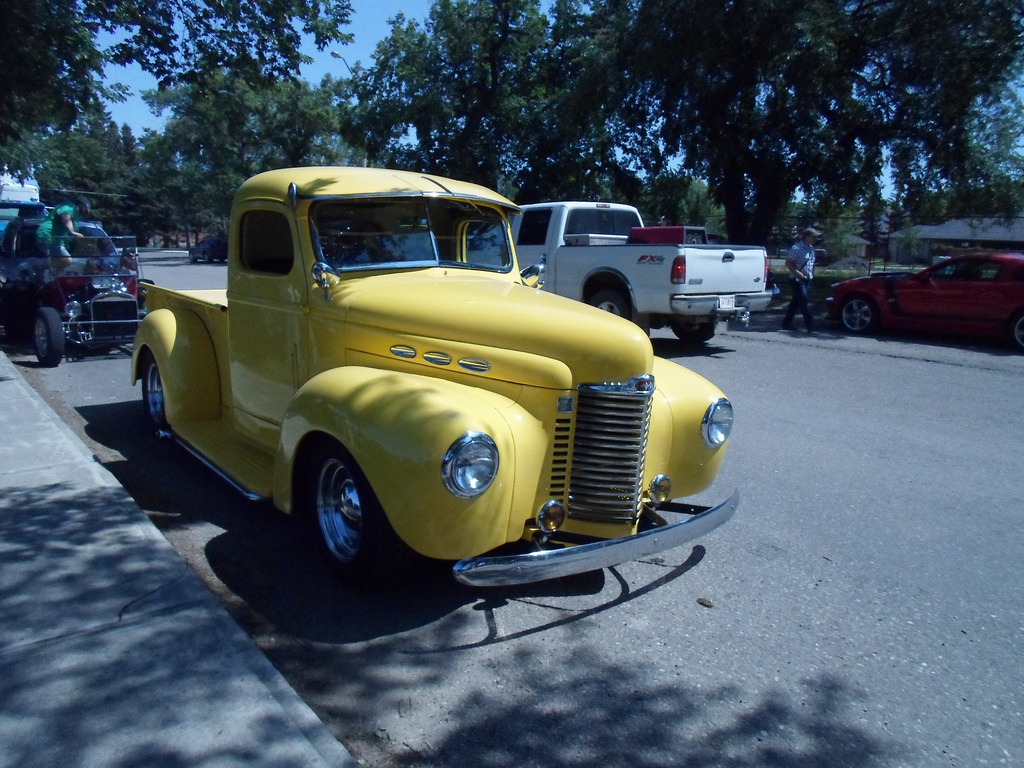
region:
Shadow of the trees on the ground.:
[507, 655, 603, 736]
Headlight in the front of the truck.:
[436, 435, 509, 499]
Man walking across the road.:
[779, 211, 818, 341]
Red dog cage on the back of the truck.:
[619, 205, 708, 244]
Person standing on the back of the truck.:
[41, 195, 98, 276]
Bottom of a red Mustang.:
[840, 315, 1021, 355]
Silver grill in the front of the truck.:
[508, 351, 676, 560]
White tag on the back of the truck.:
[713, 277, 749, 315]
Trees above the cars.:
[747, 18, 749, 19]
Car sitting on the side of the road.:
[175, 206, 239, 270]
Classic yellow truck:
[133, 164, 732, 589]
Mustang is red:
[832, 250, 1020, 348]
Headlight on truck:
[441, 433, 502, 495]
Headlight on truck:
[702, 395, 732, 446]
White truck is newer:
[516, 202, 769, 323]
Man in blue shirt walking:
[788, 227, 818, 333]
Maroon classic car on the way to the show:
[7, 253, 150, 364]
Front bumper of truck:
[453, 483, 745, 586]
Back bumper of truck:
[669, 294, 780, 318]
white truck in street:
[509, 195, 779, 347]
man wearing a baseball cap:
[780, 220, 831, 331]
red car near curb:
[821, 245, 1021, 360]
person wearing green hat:
[45, 201, 87, 263]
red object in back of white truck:
[631, 217, 715, 255]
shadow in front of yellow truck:
[353, 662, 946, 767]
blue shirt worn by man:
[777, 240, 832, 285]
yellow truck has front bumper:
[445, 483, 774, 597]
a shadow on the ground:
[502, 667, 681, 762]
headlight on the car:
[442, 430, 494, 497]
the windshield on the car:
[312, 204, 439, 265]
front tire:
[301, 454, 385, 579]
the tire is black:
[300, 446, 384, 573]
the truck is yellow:
[162, 137, 716, 572]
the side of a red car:
[820, 247, 1020, 353]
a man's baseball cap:
[800, 225, 826, 241]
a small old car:
[27, 225, 161, 358]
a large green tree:
[140, 54, 346, 188]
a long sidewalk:
[0, 357, 359, 766]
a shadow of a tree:
[392, 645, 870, 764]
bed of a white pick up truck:
[521, 202, 778, 342]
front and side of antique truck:
[133, 167, 740, 589]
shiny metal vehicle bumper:
[456, 490, 738, 586]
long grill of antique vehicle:
[563, 376, 655, 523]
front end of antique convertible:
[26, 233, 148, 363]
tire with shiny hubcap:
[301, 438, 394, 591]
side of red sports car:
[831, 253, 1018, 337]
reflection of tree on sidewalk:
[1, 480, 343, 765]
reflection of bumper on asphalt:
[414, 543, 708, 662]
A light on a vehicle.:
[441, 438, 503, 495]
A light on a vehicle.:
[528, 491, 573, 543]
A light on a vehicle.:
[710, 403, 748, 451]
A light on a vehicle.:
[667, 248, 684, 288]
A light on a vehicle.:
[758, 253, 782, 283]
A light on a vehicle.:
[66, 299, 86, 325]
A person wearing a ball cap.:
[777, 213, 831, 334]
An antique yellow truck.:
[125, 140, 754, 669]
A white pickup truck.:
[502, 194, 788, 372]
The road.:
[4, 218, 1022, 762]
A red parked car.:
[817, 229, 1021, 376]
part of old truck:
[441, 432, 499, 499]